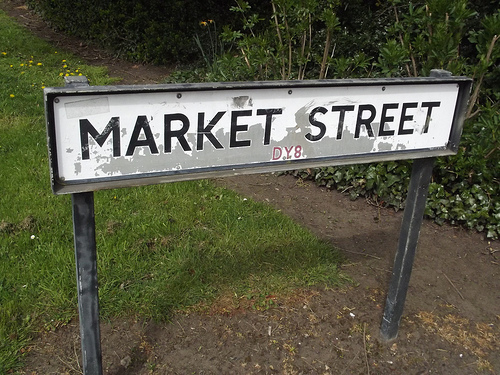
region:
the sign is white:
[83, 105, 198, 236]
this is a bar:
[64, 206, 139, 315]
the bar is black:
[9, 191, 165, 366]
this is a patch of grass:
[268, 220, 284, 253]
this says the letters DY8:
[241, 130, 310, 189]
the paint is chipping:
[233, 77, 390, 237]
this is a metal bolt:
[172, 25, 227, 160]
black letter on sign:
[74, 114, 123, 158]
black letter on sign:
[123, 115, 158, 157]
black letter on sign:
[161, 112, 191, 152]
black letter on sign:
[191, 110, 226, 151]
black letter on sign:
[228, 110, 250, 147]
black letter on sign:
[255, 108, 280, 143]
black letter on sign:
[306, 108, 327, 142]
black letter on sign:
[331, 102, 353, 139]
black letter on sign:
[352, 104, 377, 139]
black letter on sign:
[378, 103, 399, 135]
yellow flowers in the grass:
[15, 53, 74, 93]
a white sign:
[54, 74, 466, 176]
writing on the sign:
[81, 109, 449, 141]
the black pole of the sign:
[392, 155, 429, 350]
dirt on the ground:
[143, 318, 345, 353]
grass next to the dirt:
[107, 193, 322, 272]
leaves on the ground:
[436, 168, 491, 213]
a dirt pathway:
[101, 48, 476, 311]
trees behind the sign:
[203, 11, 478, 67]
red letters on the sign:
[271, 144, 303, 156]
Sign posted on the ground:
[43, 66, 467, 369]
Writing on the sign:
[74, 99, 441, 164]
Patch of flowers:
[172, 18, 497, 249]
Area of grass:
[0, 19, 346, 369]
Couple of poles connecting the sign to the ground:
[66, 160, 438, 371]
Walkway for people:
[10, 62, 499, 372]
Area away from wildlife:
[0, 0, 499, 370]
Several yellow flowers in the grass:
[2, 41, 84, 103]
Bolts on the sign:
[176, 84, 390, 100]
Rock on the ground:
[119, 353, 134, 372]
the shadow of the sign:
[119, 230, 396, 373]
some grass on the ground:
[125, 215, 271, 277]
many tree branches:
[239, 18, 461, 59]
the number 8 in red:
[294, 140, 301, 159]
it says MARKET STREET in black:
[79, 103, 439, 160]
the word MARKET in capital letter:
[79, 108, 281, 160]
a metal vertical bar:
[76, 196, 101, 371]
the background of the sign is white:
[52, 85, 469, 176]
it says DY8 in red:
[272, 143, 301, 160]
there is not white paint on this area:
[204, 150, 264, 162]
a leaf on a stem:
[379, 45, 392, 63]